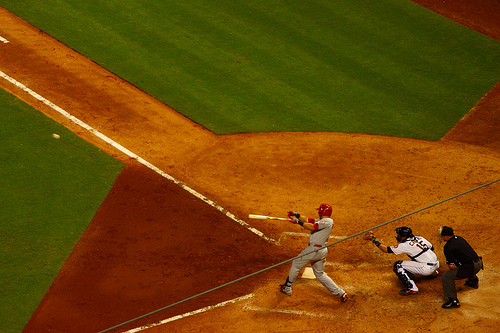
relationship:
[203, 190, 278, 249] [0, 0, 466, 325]
line drawn on baseball field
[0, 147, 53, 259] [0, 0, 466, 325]
grass on baseball field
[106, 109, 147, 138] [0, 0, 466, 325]
dirt on baseball field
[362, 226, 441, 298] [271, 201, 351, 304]
catcher behind batter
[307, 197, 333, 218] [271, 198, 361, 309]
helmet on baseball batter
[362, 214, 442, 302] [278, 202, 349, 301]
catcher behind baseball batter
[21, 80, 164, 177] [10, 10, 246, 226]
stripes on field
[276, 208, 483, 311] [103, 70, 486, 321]
people playing game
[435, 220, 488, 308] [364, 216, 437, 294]
umpire behind catcher